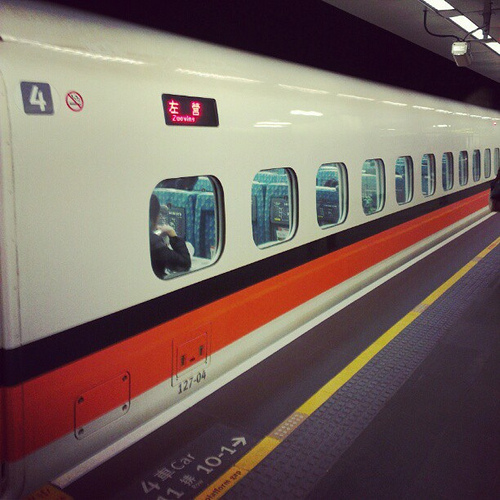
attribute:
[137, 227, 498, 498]
line — yellow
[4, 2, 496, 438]
train — red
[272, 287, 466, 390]
line — yellow 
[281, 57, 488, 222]
train — orange 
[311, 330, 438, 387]
mark — Yellow 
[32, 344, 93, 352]
line — orange 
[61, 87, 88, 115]
sign — smoke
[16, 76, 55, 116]
number — 4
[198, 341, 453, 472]
yellow line — Yellow 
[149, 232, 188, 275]
top — long-sleeved